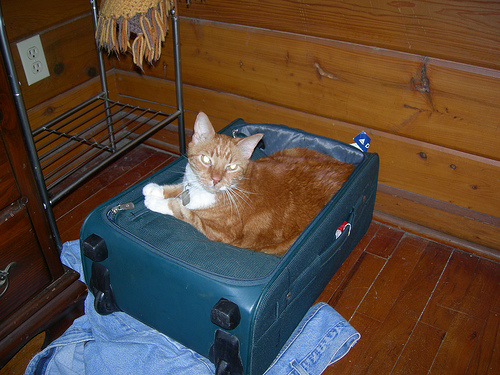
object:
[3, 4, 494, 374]
picture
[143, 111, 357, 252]
cat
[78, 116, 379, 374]
suitcase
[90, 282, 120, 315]
wheels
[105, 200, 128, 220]
zipper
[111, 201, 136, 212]
pull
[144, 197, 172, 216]
paws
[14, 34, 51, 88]
outlet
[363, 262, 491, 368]
floor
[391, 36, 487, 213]
wall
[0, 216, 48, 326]
drawer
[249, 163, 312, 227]
fur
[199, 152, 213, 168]
eyes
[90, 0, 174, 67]
object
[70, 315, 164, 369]
cloth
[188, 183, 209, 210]
chest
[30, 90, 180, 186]
shelf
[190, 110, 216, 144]
ears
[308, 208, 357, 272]
handle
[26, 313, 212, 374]
jeans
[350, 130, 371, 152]
tag